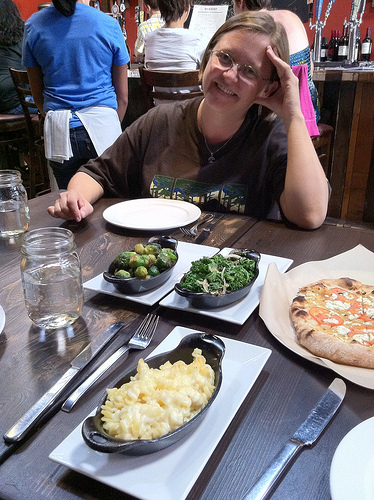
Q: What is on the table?
A: Food.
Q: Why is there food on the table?
A: Meal time.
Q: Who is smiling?
A: A woman.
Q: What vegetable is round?
A: Brussel Sprouts.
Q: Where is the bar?
A: In background.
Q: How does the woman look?
A: Happy.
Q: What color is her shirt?
A: Black.